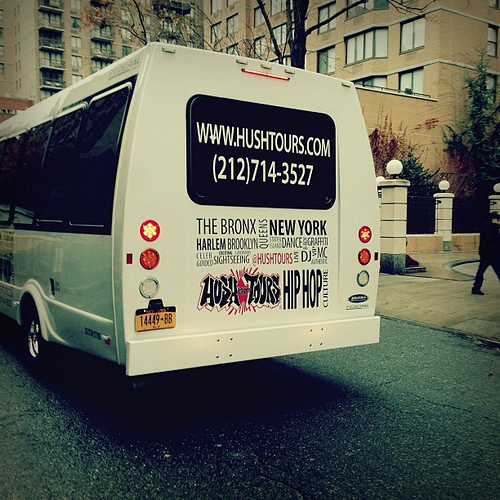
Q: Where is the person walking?
A: The sidewalk.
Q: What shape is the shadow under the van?
A: Rectangle.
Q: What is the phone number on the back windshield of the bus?
A: (212)714-3527.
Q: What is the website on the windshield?
A: Www.hushtours.com.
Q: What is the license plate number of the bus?
A: 14449-BB.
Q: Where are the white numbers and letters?
A: On the back window.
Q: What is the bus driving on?
A: A black paved road.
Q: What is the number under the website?
A: A phone number.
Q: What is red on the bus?
A: The brake lights.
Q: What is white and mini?
A: The bus.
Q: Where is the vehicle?
A: On the street.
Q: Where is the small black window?
A: The back of the bus.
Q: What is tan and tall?
A: The building.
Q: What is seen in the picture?
A: Van.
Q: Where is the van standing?
A: In the road.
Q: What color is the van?
A: White.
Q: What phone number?
A: 212-714-3527.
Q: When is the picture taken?
A: Daytime.